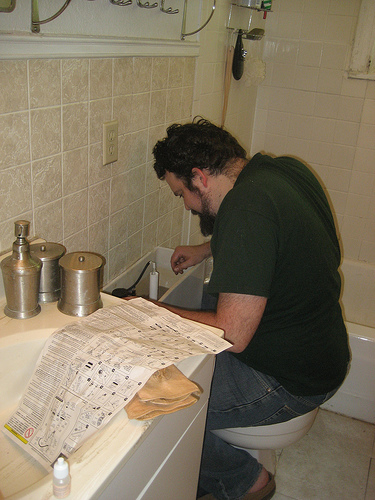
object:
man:
[152, 116, 351, 500]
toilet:
[102, 245, 320, 479]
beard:
[193, 187, 216, 237]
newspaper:
[0, 297, 233, 477]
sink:
[0, 329, 146, 500]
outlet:
[103, 120, 119, 166]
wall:
[0, 0, 258, 293]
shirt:
[205, 151, 353, 394]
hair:
[152, 116, 248, 180]